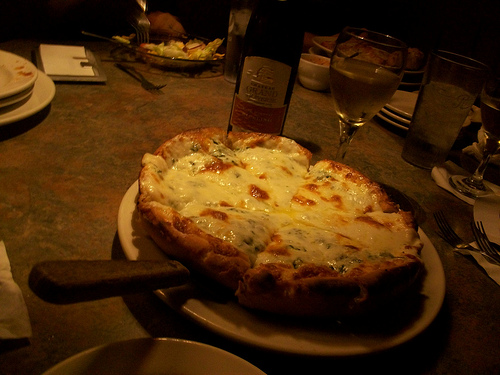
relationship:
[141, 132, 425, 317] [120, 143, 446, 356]
pizza on a plate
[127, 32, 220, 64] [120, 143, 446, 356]
salad on plate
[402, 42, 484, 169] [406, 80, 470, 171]
cup has water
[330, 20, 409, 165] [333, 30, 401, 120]
glass has wine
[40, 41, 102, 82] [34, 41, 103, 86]
paper on board